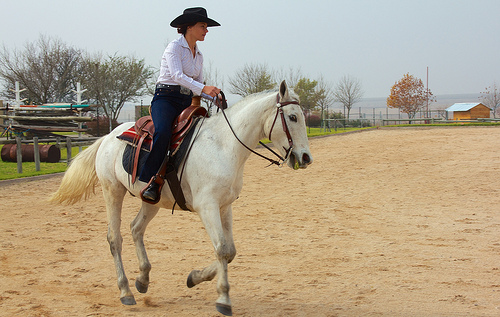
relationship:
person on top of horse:
[144, 8, 227, 200] [50, 80, 312, 316]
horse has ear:
[50, 80, 312, 316] [280, 80, 288, 100]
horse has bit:
[50, 80, 312, 316] [279, 147, 293, 167]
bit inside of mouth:
[279, 147, 293, 167] [290, 152, 308, 169]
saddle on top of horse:
[132, 96, 211, 182] [50, 80, 312, 316]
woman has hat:
[144, 8, 227, 200] [170, 8, 221, 28]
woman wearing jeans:
[144, 8, 227, 200] [139, 89, 192, 181]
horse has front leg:
[50, 80, 312, 316] [194, 204, 232, 316]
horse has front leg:
[50, 80, 312, 316] [187, 206, 235, 288]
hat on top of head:
[170, 8, 221, 28] [177, 22, 208, 42]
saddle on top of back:
[132, 96, 211, 182] [110, 116, 218, 139]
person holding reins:
[144, 8, 227, 200] [217, 91, 283, 165]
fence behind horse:
[1, 118, 499, 172] [50, 80, 312, 316]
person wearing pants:
[144, 8, 227, 200] [139, 89, 192, 181]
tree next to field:
[387, 73, 436, 124] [0, 126, 499, 316]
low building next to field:
[446, 103, 492, 124] [0, 126, 499, 316]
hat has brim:
[170, 8, 221, 28] [170, 14, 219, 26]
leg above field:
[102, 182, 136, 305] [0, 126, 499, 316]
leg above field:
[130, 202, 158, 294] [0, 126, 499, 316]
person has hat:
[144, 8, 227, 200] [170, 8, 221, 28]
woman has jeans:
[144, 8, 227, 200] [139, 89, 192, 181]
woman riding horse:
[144, 8, 227, 200] [50, 80, 312, 316]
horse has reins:
[50, 80, 312, 316] [217, 91, 283, 165]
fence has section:
[1, 118, 499, 172] [16, 138, 72, 172]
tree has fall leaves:
[387, 73, 436, 124] [387, 73, 437, 113]